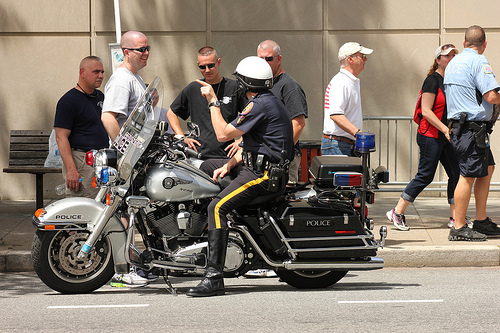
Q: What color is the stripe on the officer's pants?
A: Yellow.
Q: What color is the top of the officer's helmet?
A: White.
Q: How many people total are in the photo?
A: Eight.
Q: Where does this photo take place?
A: Street.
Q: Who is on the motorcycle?
A: Officer.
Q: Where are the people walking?
A: Sidewalk.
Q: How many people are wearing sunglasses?
A: Three.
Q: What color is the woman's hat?
A: White.